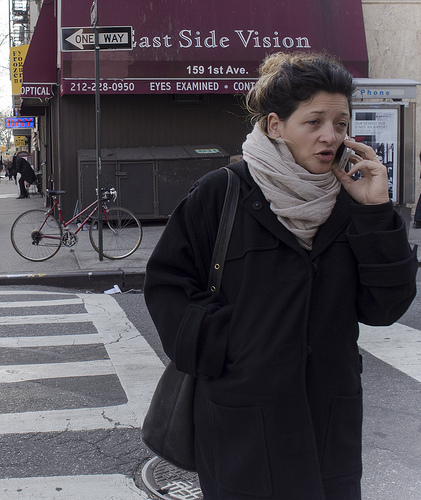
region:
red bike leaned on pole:
[3, 184, 149, 265]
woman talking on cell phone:
[240, 57, 362, 173]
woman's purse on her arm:
[133, 155, 241, 470]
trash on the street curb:
[80, 281, 143, 296]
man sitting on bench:
[2, 152, 45, 204]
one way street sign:
[60, 23, 136, 52]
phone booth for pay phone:
[344, 76, 419, 201]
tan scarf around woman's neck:
[237, 124, 342, 244]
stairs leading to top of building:
[6, 1, 33, 46]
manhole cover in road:
[128, 445, 210, 497]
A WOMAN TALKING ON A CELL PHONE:
[139, 47, 418, 495]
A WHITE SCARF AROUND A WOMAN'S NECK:
[235, 46, 349, 250]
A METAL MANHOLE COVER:
[137, 455, 206, 498]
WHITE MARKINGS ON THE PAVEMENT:
[3, 281, 158, 496]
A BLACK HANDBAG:
[138, 165, 244, 471]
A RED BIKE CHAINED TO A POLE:
[9, 184, 146, 263]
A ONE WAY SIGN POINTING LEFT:
[55, 21, 136, 54]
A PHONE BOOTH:
[348, 75, 419, 197]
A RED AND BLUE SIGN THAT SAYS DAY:
[3, 112, 39, 133]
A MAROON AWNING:
[57, 6, 371, 100]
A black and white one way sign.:
[60, 26, 134, 49]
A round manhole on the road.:
[141, 454, 207, 499]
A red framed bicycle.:
[12, 185, 143, 266]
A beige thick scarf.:
[243, 125, 345, 247]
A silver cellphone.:
[342, 133, 353, 169]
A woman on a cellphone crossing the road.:
[131, 50, 418, 497]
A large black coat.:
[144, 156, 420, 498]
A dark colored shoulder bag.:
[141, 160, 243, 473]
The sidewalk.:
[0, 148, 186, 273]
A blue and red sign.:
[5, 118, 34, 127]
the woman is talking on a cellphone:
[293, 95, 377, 199]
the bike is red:
[47, 197, 121, 234]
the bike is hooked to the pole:
[79, 183, 126, 234]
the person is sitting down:
[4, 153, 44, 195]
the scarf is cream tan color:
[262, 162, 305, 199]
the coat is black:
[227, 373, 285, 436]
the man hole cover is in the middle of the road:
[129, 448, 218, 499]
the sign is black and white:
[55, 23, 144, 60]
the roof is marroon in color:
[180, 3, 219, 21]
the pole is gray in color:
[86, 113, 112, 152]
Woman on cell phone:
[224, 36, 403, 232]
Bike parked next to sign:
[11, 176, 152, 269]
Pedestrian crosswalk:
[0, 276, 169, 499]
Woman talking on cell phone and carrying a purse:
[139, 50, 419, 498]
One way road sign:
[52, 19, 154, 58]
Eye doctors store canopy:
[55, 0, 380, 105]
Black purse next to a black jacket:
[132, 160, 237, 484]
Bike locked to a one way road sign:
[7, 6, 165, 283]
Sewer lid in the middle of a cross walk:
[103, 433, 250, 497]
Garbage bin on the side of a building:
[67, 142, 162, 234]